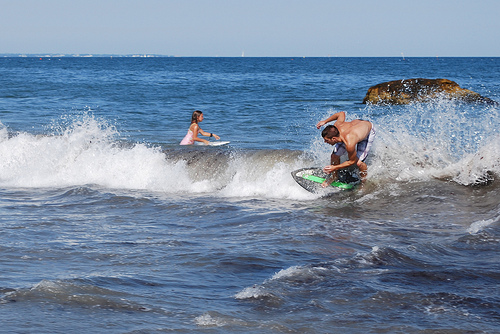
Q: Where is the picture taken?
A: Ocean.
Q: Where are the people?
A: In the water.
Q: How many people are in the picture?
A: 2.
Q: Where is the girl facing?
A: Right.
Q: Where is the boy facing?
A: Left.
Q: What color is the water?
A: Blue.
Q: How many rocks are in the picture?
A: 1.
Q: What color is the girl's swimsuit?
A: White.